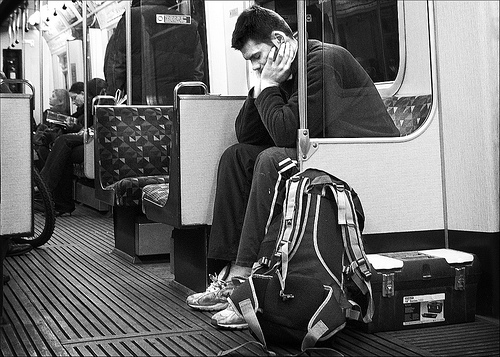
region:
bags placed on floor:
[220, 155, 497, 343]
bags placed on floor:
[290, 158, 414, 329]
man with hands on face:
[201, 8, 376, 171]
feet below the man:
[178, 248, 255, 335]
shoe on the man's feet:
[178, 261, 236, 321]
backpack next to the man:
[237, 158, 385, 308]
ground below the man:
[70, 248, 150, 341]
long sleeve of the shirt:
[253, 80, 311, 142]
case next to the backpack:
[353, 221, 486, 319]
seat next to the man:
[84, 103, 146, 177]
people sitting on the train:
[45, 56, 119, 133]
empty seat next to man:
[88, 92, 176, 210]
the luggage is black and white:
[430, 283, 448, 310]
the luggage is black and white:
[386, 283, 410, 312]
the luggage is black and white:
[404, 270, 427, 308]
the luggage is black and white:
[389, 243, 419, 308]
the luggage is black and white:
[404, 274, 415, 315]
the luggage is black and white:
[412, 281, 428, 309]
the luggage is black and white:
[436, 277, 441, 290]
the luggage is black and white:
[418, 278, 439, 313]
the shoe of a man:
[181, 265, 248, 310]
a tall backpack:
[225, 156, 382, 354]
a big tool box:
[348, 242, 482, 329]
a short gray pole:
[291, 1, 308, 130]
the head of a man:
[225, 7, 304, 83]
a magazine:
[46, 106, 78, 128]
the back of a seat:
[174, 90, 251, 226]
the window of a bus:
[264, 0, 404, 98]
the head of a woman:
[67, 83, 84, 108]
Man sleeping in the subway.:
[192, 2, 400, 151]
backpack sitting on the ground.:
[235, 158, 378, 348]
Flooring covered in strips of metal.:
[27, 270, 173, 350]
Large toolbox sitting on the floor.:
[357, 241, 482, 332]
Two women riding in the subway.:
[38, 79, 88, 129]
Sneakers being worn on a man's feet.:
[177, 259, 263, 326]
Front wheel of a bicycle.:
[17, 153, 59, 258]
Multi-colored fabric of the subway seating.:
[92, 101, 174, 188]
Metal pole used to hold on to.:
[291, 2, 316, 137]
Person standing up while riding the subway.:
[103, 0, 210, 103]